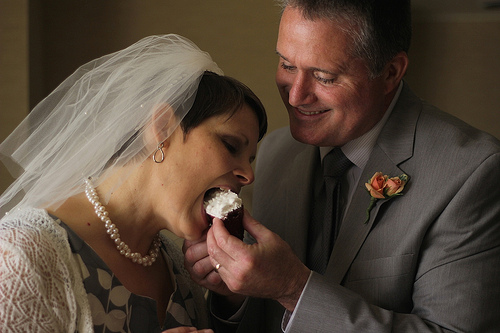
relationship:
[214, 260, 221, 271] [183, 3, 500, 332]
ring on man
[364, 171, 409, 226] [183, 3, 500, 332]
flower on man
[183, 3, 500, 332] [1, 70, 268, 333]
man feeding woman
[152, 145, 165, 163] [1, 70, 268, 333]
earring worn by woman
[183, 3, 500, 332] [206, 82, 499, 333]
man in h suit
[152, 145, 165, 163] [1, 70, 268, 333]
earring on woman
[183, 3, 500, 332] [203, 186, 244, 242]
man sharing cake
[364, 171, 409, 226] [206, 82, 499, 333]
flower on suit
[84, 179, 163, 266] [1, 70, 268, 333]
necklace on woman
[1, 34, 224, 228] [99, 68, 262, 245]
veil on her head